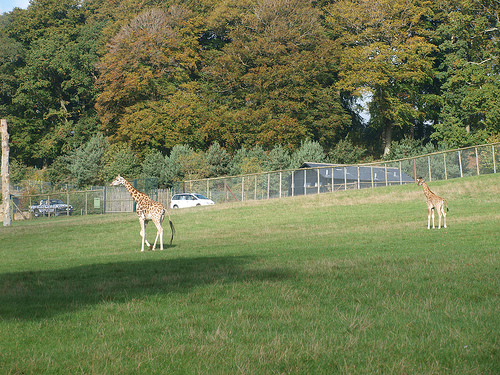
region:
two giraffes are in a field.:
[108, 173, 452, 252]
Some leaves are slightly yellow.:
[93, 2, 438, 149]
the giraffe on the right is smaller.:
[111, 174, 451, 253]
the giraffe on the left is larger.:
[108, 173, 448, 253]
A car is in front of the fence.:
[168, 178, 218, 207]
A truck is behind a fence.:
[27, 187, 75, 217]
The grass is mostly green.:
[0, 181, 498, 373]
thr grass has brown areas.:
[1, 177, 497, 372]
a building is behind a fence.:
[290, 159, 415, 199]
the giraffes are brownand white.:
[110, 172, 449, 269]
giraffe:
[101, 172, 188, 257]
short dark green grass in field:
[232, 336, 280, 364]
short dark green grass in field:
[340, 241, 378, 285]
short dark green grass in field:
[351, 308, 409, 326]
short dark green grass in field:
[268, 291, 316, 311]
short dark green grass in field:
[150, 261, 208, 309]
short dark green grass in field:
[70, 325, 105, 346]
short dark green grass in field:
[71, 292, 123, 322]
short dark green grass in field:
[220, 291, 271, 332]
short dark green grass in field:
[292, 276, 360, 318]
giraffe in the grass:
[412, 169, 444, 234]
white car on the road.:
[165, 187, 216, 214]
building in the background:
[280, 148, 415, 198]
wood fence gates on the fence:
[103, 185, 170, 215]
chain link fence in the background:
[174, 138, 493, 206]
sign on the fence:
[90, 195, 105, 210]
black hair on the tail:
[167, 212, 180, 250]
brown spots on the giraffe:
[108, 172, 178, 253]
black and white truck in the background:
[20, 194, 80, 221]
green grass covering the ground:
[0, 175, 497, 369]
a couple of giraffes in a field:
[107, 171, 451, 249]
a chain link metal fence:
[249, 159, 414, 201]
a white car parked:
[171, 191, 215, 209]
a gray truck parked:
[32, 195, 72, 219]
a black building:
[287, 161, 414, 191]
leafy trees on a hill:
[121, 19, 341, 150]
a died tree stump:
[0, 118, 8, 226]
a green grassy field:
[190, 263, 442, 355]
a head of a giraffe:
[107, 171, 125, 187]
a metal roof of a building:
[322, 163, 412, 177]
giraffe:
[90, 166, 178, 256]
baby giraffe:
[401, 165, 463, 263]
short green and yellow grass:
[202, 296, 263, 340]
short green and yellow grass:
[331, 268, 361, 293]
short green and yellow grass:
[382, 299, 462, 346]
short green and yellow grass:
[312, 313, 399, 371]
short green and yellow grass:
[121, 318, 185, 372]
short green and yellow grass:
[270, 263, 308, 304]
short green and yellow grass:
[111, 259, 146, 297]